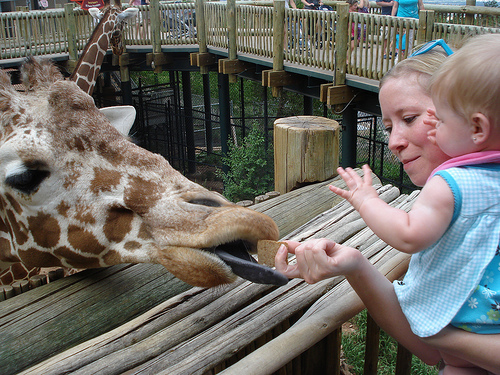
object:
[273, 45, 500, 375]
woman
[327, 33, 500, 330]
baby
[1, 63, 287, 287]
giraffe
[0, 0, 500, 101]
fence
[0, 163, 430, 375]
fence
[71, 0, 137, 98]
giraffe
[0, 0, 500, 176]
background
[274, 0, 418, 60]
people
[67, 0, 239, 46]
people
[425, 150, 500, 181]
bib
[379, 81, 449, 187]
face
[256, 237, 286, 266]
treat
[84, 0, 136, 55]
head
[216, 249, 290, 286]
tongue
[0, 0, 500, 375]
giraffe and people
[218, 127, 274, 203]
tree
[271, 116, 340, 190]
post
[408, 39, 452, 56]
sunglasses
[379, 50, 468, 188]
head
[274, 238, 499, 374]
arms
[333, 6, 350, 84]
post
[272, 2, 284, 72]
post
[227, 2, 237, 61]
post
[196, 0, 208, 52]
post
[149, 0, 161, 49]
post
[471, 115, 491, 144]
ear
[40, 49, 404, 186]
fence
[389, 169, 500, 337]
dress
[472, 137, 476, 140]
earring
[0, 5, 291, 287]
giraffes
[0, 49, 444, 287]
enclosure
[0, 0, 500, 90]
boardwalk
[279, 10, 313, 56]
stroller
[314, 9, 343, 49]
stroller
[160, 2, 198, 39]
stroller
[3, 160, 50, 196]
eye